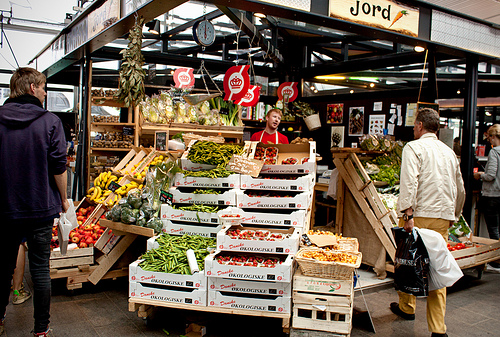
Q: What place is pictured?
A: It is a shop.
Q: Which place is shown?
A: It is a shop.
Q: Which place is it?
A: It is a shop.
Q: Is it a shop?
A: Yes, it is a shop.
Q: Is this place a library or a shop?
A: It is a shop.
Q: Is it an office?
A: No, it is a shop.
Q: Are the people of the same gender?
A: No, they are both male and female.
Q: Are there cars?
A: No, there are no cars.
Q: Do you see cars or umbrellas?
A: No, there are no cars or umbrellas.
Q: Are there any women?
A: Yes, there is a woman.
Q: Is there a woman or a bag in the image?
A: Yes, there is a woman.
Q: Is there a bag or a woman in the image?
A: Yes, there is a woman.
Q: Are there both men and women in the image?
A: Yes, there are both a woman and a man.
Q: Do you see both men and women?
A: Yes, there are both a woman and a man.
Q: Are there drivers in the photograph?
A: No, there are no drivers.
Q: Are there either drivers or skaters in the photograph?
A: No, there are no drivers or skaters.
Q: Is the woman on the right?
A: Yes, the woman is on the right of the image.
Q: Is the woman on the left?
A: No, the woman is on the right of the image.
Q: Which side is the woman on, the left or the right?
A: The woman is on the right of the image.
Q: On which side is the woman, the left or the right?
A: The woman is on the right of the image.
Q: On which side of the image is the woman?
A: The woman is on the right of the image.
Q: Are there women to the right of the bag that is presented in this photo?
A: Yes, there is a woman to the right of the bag.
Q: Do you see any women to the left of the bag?
A: No, the woman is to the right of the bag.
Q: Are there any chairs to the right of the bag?
A: No, there is a woman to the right of the bag.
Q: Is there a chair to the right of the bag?
A: No, there is a woman to the right of the bag.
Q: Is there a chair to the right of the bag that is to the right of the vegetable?
A: No, there is a woman to the right of the bag.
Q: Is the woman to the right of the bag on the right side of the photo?
A: Yes, the woman is to the right of the bag.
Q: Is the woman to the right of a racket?
A: No, the woman is to the right of the bag.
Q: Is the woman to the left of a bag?
A: No, the woman is to the right of a bag.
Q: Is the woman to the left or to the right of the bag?
A: The woman is to the right of the bag.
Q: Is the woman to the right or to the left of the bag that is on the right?
A: The woman is to the right of the bag.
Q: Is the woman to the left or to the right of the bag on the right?
A: The woman is to the right of the bag.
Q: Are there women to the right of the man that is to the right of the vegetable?
A: Yes, there is a woman to the right of the man.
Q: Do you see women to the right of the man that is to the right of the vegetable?
A: Yes, there is a woman to the right of the man.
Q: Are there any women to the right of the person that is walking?
A: Yes, there is a woman to the right of the man.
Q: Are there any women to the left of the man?
A: No, the woman is to the right of the man.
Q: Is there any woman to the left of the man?
A: No, the woman is to the right of the man.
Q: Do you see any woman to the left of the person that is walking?
A: No, the woman is to the right of the man.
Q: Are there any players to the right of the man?
A: No, there is a woman to the right of the man.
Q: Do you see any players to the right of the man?
A: No, there is a woman to the right of the man.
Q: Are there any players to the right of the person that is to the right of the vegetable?
A: No, there is a woman to the right of the man.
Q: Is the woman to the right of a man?
A: Yes, the woman is to the right of a man.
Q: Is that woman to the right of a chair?
A: No, the woman is to the right of a man.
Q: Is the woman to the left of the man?
A: No, the woman is to the right of the man.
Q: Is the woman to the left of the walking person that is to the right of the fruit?
A: No, the woman is to the right of the man.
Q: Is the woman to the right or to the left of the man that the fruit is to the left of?
A: The woman is to the right of the man.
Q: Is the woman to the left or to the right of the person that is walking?
A: The woman is to the right of the man.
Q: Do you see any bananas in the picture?
A: Yes, there is a banana.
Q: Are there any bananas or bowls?
A: Yes, there is a banana.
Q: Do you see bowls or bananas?
A: Yes, there is a banana.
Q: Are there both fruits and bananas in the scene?
A: Yes, there are both a banana and a fruit.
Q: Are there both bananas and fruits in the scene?
A: Yes, there are both a banana and a fruit.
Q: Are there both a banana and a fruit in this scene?
A: Yes, there are both a banana and a fruit.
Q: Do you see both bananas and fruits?
A: Yes, there are both a banana and a fruit.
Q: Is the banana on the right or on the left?
A: The banana is on the left of the image.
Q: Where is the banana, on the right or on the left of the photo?
A: The banana is on the left of the image.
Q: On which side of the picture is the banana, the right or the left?
A: The banana is on the left of the image.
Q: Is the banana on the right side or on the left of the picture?
A: The banana is on the left of the image.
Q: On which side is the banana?
A: The banana is on the left of the image.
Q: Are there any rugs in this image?
A: No, there are no rugs.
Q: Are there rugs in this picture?
A: No, there are no rugs.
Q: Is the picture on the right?
A: Yes, the picture is on the right of the image.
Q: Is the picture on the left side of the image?
A: No, the picture is on the right of the image.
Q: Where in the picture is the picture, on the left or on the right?
A: The picture is on the right of the image.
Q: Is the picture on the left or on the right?
A: The picture is on the right of the image.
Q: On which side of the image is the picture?
A: The picture is on the right of the image.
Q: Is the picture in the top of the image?
A: Yes, the picture is in the top of the image.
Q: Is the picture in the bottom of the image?
A: No, the picture is in the top of the image.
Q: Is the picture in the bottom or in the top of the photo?
A: The picture is in the top of the image.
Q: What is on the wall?
A: The picture is on the wall.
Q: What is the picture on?
A: The picture is on the wall.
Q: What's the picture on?
A: The picture is on the wall.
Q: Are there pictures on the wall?
A: Yes, there is a picture on the wall.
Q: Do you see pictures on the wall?
A: Yes, there is a picture on the wall.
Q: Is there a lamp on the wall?
A: No, there is a picture on the wall.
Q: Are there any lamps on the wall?
A: No, there is a picture on the wall.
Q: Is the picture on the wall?
A: Yes, the picture is on the wall.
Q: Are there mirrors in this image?
A: No, there are no mirrors.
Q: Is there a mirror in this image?
A: No, there are no mirrors.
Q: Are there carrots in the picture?
A: Yes, there is a carrot.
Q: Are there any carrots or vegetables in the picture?
A: Yes, there is a carrot.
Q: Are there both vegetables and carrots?
A: Yes, there are both a carrot and vegetables.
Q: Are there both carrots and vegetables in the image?
A: Yes, there are both a carrot and vegetables.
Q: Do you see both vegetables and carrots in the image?
A: Yes, there are both a carrot and vegetables.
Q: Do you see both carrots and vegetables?
A: Yes, there are both a carrot and vegetables.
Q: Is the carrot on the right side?
A: Yes, the carrot is on the right of the image.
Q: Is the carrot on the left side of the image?
A: No, the carrot is on the right of the image.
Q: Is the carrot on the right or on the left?
A: The carrot is on the right of the image.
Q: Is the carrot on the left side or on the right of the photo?
A: The carrot is on the right of the image.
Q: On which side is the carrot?
A: The carrot is on the right of the image.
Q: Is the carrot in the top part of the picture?
A: Yes, the carrot is in the top of the image.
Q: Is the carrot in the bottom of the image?
A: No, the carrot is in the top of the image.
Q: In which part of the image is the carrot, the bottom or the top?
A: The carrot is in the top of the image.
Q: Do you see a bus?
A: No, there are no buses.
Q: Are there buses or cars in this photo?
A: No, there are no buses or cars.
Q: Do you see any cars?
A: No, there are no cars.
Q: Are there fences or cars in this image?
A: No, there are no cars or fences.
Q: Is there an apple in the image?
A: Yes, there is an apple.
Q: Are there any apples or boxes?
A: Yes, there is an apple.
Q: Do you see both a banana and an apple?
A: Yes, there are both an apple and a banana.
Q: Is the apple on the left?
A: Yes, the apple is on the left of the image.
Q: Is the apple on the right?
A: No, the apple is on the left of the image.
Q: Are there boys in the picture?
A: No, there are no boys.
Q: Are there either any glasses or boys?
A: No, there are no boys or glasses.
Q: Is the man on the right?
A: Yes, the man is on the right of the image.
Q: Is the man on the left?
A: No, the man is on the right of the image.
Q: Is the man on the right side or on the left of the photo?
A: The man is on the right of the image.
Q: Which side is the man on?
A: The man is on the right of the image.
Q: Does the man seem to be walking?
A: Yes, the man is walking.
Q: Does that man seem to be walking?
A: Yes, the man is walking.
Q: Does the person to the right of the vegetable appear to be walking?
A: Yes, the man is walking.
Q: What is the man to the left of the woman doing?
A: The man is walking.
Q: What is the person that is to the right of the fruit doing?
A: The man is walking.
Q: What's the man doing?
A: The man is walking.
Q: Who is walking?
A: The man is walking.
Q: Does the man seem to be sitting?
A: No, the man is walking.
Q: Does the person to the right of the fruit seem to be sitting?
A: No, the man is walking.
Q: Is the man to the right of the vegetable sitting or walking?
A: The man is walking.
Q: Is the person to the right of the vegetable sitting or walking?
A: The man is walking.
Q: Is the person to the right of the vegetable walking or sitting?
A: The man is walking.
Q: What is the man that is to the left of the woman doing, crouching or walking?
A: The man is walking.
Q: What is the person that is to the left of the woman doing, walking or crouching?
A: The man is walking.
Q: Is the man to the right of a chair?
A: No, the man is to the right of the vegetable.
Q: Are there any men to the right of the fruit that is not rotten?
A: Yes, there is a man to the right of the fruit.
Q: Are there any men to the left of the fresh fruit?
A: No, the man is to the right of the fruit.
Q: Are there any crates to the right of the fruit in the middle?
A: No, there is a man to the right of the fruit.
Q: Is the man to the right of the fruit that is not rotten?
A: Yes, the man is to the right of the fruit.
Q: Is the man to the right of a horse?
A: No, the man is to the right of the fruit.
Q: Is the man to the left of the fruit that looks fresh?
A: No, the man is to the right of the fruit.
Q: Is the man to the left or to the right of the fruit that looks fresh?
A: The man is to the right of the fruit.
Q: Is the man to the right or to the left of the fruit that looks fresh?
A: The man is to the right of the fruit.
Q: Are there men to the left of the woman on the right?
A: Yes, there is a man to the left of the woman.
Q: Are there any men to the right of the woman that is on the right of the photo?
A: No, the man is to the left of the woman.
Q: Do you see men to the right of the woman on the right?
A: No, the man is to the left of the woman.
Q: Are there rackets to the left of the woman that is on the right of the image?
A: No, there is a man to the left of the woman.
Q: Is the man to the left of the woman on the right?
A: Yes, the man is to the left of the woman.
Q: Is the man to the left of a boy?
A: No, the man is to the left of the woman.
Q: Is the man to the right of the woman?
A: No, the man is to the left of the woman.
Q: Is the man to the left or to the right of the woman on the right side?
A: The man is to the left of the woman.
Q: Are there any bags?
A: Yes, there is a bag.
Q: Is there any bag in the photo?
A: Yes, there is a bag.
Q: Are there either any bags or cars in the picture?
A: Yes, there is a bag.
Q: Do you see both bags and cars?
A: No, there is a bag but no cars.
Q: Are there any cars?
A: No, there are no cars.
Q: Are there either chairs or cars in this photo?
A: No, there are no cars or chairs.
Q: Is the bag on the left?
A: No, the bag is on the right of the image.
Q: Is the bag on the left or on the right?
A: The bag is on the right of the image.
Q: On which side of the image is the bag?
A: The bag is on the right of the image.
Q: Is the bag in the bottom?
A: Yes, the bag is in the bottom of the image.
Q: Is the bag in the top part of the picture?
A: No, the bag is in the bottom of the image.